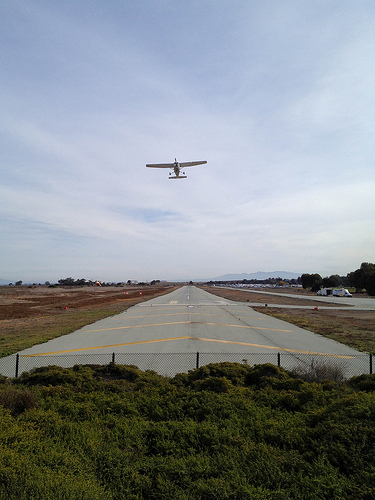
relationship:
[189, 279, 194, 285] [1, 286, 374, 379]
bush behind runway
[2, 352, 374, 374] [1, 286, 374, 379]
fence by runway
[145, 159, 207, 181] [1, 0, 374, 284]
airplane in sky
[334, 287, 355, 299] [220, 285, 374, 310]
truck on runway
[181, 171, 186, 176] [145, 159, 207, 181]
wheel on plane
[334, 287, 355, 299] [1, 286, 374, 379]
truck next to runway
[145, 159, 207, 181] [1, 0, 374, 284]
plane in sky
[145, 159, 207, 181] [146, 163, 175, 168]
plane has a wing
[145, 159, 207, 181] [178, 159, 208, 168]
plane has a wing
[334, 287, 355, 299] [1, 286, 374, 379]
truck by runway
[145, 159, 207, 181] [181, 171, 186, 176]
plane has a wheel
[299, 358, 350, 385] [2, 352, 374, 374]
tree by fence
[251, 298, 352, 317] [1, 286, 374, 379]
road by runway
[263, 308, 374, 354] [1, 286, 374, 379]
grass by runway